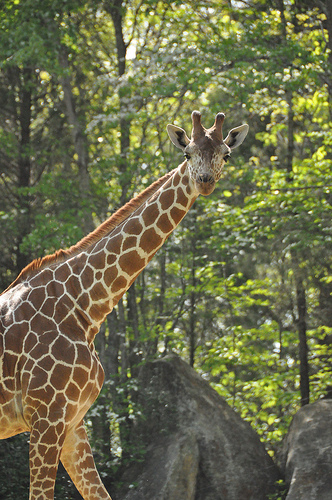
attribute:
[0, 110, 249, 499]
giraffe — standing, patterned, brown, cream, posing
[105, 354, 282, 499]
boulder — big, gray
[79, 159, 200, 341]
neck — long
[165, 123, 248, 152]
ears — perked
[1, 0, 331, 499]
trees — green, tall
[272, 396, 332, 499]
boulder — gray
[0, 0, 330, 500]
area — lit